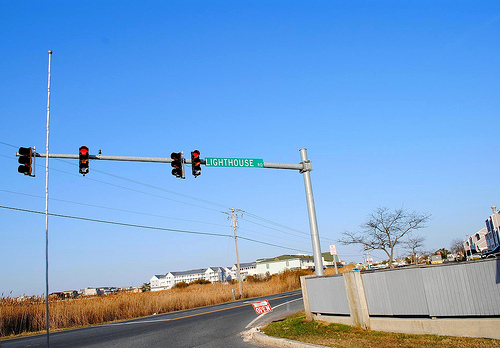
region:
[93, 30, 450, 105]
The sky is clear and blue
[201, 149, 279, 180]
The sign on the pole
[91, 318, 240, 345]
The street is made of asphalt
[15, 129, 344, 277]
The pole is made of metal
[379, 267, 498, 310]
The gate is the color white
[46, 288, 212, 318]
The grass is tall and yellow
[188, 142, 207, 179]
The traffic light is on red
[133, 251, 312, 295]
The building is the color white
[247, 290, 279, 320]
The sign on the side of the road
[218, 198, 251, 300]
The electrical pole in the ground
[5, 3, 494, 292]
blue of daytime sky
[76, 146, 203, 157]
two glowing red lights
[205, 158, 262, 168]
green and white sign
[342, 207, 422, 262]
tree with no leaves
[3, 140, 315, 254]
wires on telephone pole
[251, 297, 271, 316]
red and white sign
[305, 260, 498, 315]
surface of white wall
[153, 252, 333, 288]
white buildings on horizon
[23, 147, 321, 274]
horizontal pole on vertical pole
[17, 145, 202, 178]
four traffic lights on pole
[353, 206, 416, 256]
trees with branches and leaves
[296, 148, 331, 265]
grey color metal post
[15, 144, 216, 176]
red color signal light in the pole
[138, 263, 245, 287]
lot of buildings with windows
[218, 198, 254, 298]
electric pole with cable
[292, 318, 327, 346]
dirt with grass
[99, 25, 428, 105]
a clear blue sky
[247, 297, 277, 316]
red color square board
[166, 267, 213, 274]
roof of the building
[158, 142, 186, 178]
A black traffic signal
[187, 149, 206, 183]
A black traffic signal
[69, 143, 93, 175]
A black traffic signal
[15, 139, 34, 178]
A black traffic signal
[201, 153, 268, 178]
A blue road sign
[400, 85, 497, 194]
A light blue sky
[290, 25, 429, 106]
A light blue sky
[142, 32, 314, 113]
A light blue sky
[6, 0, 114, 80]
A light blue sky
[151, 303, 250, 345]
A grey smooth road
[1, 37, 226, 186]
this is a street lamp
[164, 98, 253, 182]
this is a street sign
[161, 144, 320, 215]
the sign is green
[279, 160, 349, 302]
the pole is metal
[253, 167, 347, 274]
the pole is silver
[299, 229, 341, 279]
the pole is grey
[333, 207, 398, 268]
this is an old tree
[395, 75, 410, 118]
this has no clouds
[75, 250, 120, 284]
the sky is very clear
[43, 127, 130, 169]
the light is red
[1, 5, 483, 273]
The clear sky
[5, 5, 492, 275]
A clear sky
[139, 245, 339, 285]
A set of houses in the background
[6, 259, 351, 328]
The brown high grass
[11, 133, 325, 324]
traffice lights on silver pole indicating STOP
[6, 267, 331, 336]
brown corn field next to road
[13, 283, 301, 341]
grey black concrete road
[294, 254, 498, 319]
silver metal fence with cream cement posts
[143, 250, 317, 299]
large block of white apartments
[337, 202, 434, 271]
leafless tree in background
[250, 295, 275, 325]
red sign with white lettering on side of road